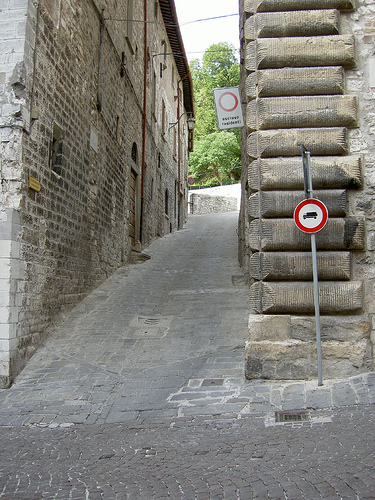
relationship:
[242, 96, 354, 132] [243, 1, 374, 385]
brick along wall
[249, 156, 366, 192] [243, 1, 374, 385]
brick along wall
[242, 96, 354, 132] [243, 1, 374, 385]
brick along side of wall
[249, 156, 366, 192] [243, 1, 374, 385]
brick along side of wall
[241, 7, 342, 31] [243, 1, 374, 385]
brick along side of wall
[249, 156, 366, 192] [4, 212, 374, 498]
brick by road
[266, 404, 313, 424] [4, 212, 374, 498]
drain on road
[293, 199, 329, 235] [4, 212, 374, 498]
sign on road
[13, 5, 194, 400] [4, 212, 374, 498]
wall on road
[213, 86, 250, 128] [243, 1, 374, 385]
sign on wall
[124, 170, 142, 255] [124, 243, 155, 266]
door has steps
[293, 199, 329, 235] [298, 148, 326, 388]
sign mounted on pole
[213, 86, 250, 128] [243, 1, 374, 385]
sign mounted on wall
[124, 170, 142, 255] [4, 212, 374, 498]
door in road